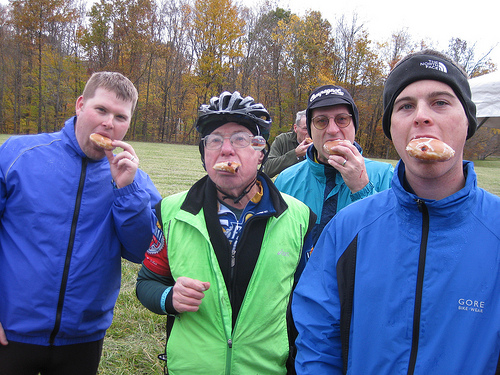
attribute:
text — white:
[435, 275, 494, 340]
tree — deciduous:
[124, 12, 279, 88]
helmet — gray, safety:
[184, 75, 304, 155]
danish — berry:
[383, 139, 474, 172]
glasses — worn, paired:
[190, 129, 280, 159]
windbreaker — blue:
[25, 154, 122, 302]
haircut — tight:
[64, 79, 155, 125]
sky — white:
[372, 0, 462, 32]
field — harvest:
[161, 147, 217, 205]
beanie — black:
[371, 52, 473, 121]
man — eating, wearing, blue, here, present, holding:
[349, 61, 496, 323]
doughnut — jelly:
[199, 144, 267, 197]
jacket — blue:
[366, 182, 475, 358]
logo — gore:
[424, 290, 493, 330]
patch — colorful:
[136, 228, 180, 261]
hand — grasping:
[148, 232, 228, 313]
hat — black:
[291, 74, 375, 134]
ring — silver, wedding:
[329, 150, 352, 173]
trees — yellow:
[204, 8, 268, 65]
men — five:
[39, 64, 467, 255]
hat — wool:
[375, 48, 456, 101]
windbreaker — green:
[152, 227, 274, 349]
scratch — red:
[350, 166, 384, 200]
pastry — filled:
[197, 149, 280, 191]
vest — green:
[148, 187, 325, 342]